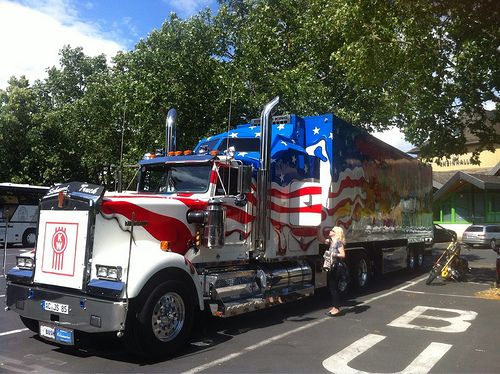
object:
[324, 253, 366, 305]
wheel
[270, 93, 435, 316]
trailer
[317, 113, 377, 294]
front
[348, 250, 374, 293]
wheel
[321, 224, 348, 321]
woman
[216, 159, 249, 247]
door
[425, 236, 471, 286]
motorbike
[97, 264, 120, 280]
left light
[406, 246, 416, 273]
wheels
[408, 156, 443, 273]
back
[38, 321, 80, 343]
plate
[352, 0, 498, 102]
branches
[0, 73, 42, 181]
tree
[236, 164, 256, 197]
mirror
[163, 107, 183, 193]
pipes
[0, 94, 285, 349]
cab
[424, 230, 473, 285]
motorcycle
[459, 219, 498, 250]
car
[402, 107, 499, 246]
building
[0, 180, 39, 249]
bus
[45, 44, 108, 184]
trees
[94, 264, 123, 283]
headlights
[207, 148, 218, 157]
lights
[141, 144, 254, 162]
top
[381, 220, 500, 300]
part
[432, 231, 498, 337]
road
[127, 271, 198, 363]
wheel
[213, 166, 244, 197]
window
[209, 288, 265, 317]
steps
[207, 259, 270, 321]
staircase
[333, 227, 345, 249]
hair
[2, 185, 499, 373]
lot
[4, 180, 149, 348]
front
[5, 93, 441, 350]
vehicle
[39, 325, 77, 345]
plates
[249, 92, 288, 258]
pipe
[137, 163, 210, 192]
windshield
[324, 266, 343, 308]
pants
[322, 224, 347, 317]
person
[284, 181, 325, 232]
compartment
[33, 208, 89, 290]
cover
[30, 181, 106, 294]
grill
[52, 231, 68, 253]
kw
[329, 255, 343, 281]
purse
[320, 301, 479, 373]
bu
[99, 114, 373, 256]
flag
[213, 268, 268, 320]
boards